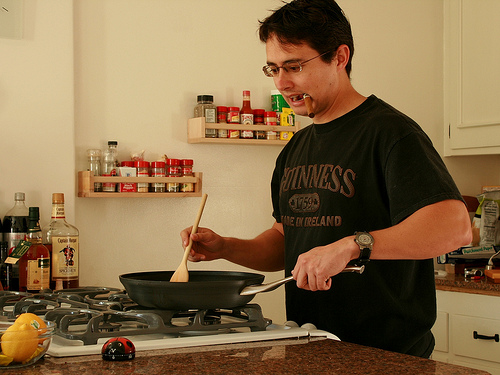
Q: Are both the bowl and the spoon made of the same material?
A: No, the bowl is made of glass and the spoon is made of wood.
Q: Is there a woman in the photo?
A: No, there are no women.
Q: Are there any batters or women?
A: No, there are no women or batters.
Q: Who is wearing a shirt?
A: The man is wearing a shirt.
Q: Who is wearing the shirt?
A: The man is wearing a shirt.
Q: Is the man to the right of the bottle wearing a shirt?
A: Yes, the man is wearing a shirt.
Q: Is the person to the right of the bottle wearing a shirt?
A: Yes, the man is wearing a shirt.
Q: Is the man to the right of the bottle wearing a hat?
A: No, the man is wearing a shirt.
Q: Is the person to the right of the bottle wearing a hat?
A: No, the man is wearing a shirt.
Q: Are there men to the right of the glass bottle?
A: Yes, there is a man to the right of the bottle.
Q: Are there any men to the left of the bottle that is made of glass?
A: No, the man is to the right of the bottle.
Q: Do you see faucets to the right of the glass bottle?
A: No, there is a man to the right of the bottle.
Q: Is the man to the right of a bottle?
A: Yes, the man is to the right of a bottle.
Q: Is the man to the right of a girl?
A: No, the man is to the right of a bottle.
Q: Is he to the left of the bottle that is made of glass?
A: No, the man is to the right of the bottle.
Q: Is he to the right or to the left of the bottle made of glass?
A: The man is to the right of the bottle.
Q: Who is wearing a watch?
A: The man is wearing a watch.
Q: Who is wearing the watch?
A: The man is wearing a watch.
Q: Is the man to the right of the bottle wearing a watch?
A: Yes, the man is wearing a watch.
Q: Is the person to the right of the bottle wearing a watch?
A: Yes, the man is wearing a watch.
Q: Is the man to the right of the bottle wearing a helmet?
A: No, the man is wearing a watch.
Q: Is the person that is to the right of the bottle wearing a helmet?
A: No, the man is wearing a watch.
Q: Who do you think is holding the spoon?
A: The man is holding the spoon.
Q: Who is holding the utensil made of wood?
A: The man is holding the spoon.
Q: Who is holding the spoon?
A: The man is holding the spoon.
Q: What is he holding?
A: The man is holding the spoon.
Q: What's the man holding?
A: The man is holding the spoon.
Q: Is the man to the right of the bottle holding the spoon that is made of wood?
A: Yes, the man is holding the spoon.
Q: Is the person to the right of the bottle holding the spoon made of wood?
A: Yes, the man is holding the spoon.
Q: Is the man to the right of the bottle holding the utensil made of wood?
A: Yes, the man is holding the spoon.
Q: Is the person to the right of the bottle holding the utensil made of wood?
A: Yes, the man is holding the spoon.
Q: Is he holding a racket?
A: No, the man is holding the spoon.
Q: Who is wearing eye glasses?
A: The man is wearing eye glasses.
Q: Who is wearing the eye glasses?
A: The man is wearing eye glasses.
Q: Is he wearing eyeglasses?
A: Yes, the man is wearing eyeglasses.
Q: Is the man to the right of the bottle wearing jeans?
A: No, the man is wearing eyeglasses.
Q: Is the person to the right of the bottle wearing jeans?
A: No, the man is wearing eyeglasses.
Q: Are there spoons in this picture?
A: Yes, there is a spoon.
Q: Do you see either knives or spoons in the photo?
A: Yes, there is a spoon.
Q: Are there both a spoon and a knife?
A: No, there is a spoon but no knives.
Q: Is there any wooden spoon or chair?
A: Yes, there is a wood spoon.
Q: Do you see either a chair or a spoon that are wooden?
A: Yes, the spoon is wooden.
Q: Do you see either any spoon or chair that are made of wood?
A: Yes, the spoon is made of wood.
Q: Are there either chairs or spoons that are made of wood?
A: Yes, the spoon is made of wood.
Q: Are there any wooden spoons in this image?
A: Yes, there is a wood spoon.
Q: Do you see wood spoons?
A: Yes, there is a wood spoon.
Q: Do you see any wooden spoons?
A: Yes, there is a wood spoon.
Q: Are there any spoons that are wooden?
A: Yes, there is a spoon that is wooden.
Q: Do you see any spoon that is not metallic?
A: Yes, there is a wooden spoon.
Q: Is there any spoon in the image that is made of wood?
A: Yes, there is a spoon that is made of wood.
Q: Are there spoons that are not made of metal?
A: Yes, there is a spoon that is made of wood.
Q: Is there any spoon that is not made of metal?
A: Yes, there is a spoon that is made of wood.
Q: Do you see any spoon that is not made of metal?
A: Yes, there is a spoon that is made of wood.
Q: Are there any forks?
A: No, there are no forks.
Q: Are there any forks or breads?
A: No, there are no forks or breads.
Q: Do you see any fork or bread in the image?
A: No, there are no forks or breads.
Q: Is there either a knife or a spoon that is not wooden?
A: No, there is a spoon but it is wooden.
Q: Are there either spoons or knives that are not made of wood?
A: No, there is a spoon but it is made of wood.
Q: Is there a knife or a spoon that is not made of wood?
A: No, there is a spoon but it is made of wood.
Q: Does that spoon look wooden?
A: Yes, the spoon is wooden.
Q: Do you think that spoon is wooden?
A: Yes, the spoon is wooden.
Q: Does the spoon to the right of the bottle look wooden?
A: Yes, the spoon is wooden.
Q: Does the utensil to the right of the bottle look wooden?
A: Yes, the spoon is wooden.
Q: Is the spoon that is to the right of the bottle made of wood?
A: Yes, the spoon is made of wood.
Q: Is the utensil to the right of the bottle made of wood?
A: Yes, the spoon is made of wood.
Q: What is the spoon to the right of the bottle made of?
A: The spoon is made of wood.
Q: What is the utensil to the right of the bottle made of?
A: The spoon is made of wood.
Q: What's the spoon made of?
A: The spoon is made of wood.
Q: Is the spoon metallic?
A: No, the spoon is wooden.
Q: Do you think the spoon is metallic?
A: No, the spoon is wooden.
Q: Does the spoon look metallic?
A: No, the spoon is wooden.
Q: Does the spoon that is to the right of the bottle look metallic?
A: No, the spoon is wooden.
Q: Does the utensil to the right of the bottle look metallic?
A: No, the spoon is wooden.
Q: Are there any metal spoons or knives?
A: No, there is a spoon but it is wooden.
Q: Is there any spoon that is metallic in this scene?
A: No, there is a spoon but it is wooden.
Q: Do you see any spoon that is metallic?
A: No, there is a spoon but it is wooden.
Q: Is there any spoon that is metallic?
A: No, there is a spoon but it is wooden.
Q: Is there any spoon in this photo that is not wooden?
A: No, there is a spoon but it is wooden.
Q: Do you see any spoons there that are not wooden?
A: No, there is a spoon but it is wooden.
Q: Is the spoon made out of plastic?
A: No, the spoon is made of wood.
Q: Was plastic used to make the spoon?
A: No, the spoon is made of wood.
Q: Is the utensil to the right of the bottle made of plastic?
A: No, the spoon is made of wood.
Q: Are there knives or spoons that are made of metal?
A: No, there is a spoon but it is made of wood.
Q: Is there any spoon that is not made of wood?
A: No, there is a spoon but it is made of wood.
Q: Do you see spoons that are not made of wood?
A: No, there is a spoon but it is made of wood.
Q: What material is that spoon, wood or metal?
A: The spoon is made of wood.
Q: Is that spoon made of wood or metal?
A: The spoon is made of wood.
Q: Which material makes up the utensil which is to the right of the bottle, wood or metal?
A: The spoon is made of wood.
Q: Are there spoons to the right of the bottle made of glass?
A: Yes, there is a spoon to the right of the bottle.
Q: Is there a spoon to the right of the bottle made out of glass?
A: Yes, there is a spoon to the right of the bottle.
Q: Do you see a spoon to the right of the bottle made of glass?
A: Yes, there is a spoon to the right of the bottle.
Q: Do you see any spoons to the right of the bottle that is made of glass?
A: Yes, there is a spoon to the right of the bottle.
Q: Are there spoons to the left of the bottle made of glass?
A: No, the spoon is to the right of the bottle.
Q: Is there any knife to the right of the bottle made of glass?
A: No, there is a spoon to the right of the bottle.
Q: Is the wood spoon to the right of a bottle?
A: Yes, the spoon is to the right of a bottle.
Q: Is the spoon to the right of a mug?
A: No, the spoon is to the right of a bottle.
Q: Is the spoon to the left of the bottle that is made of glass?
A: No, the spoon is to the right of the bottle.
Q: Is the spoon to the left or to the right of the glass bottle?
A: The spoon is to the right of the bottle.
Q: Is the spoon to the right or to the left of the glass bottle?
A: The spoon is to the right of the bottle.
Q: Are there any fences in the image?
A: No, there are no fences.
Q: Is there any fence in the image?
A: No, there are no fences.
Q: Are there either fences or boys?
A: No, there are no fences or boys.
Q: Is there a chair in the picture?
A: No, there are no chairs.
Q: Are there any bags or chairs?
A: No, there are no chairs or bags.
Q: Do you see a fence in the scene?
A: No, there are no fences.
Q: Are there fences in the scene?
A: No, there are no fences.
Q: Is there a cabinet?
A: Yes, there is a cabinet.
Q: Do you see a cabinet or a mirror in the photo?
A: Yes, there is a cabinet.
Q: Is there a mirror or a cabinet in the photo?
A: Yes, there is a cabinet.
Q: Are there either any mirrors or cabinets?
A: Yes, there is a cabinet.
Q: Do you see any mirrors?
A: No, there are no mirrors.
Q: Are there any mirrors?
A: No, there are no mirrors.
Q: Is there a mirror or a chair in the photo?
A: No, there are no mirrors or chairs.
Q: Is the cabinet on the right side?
A: Yes, the cabinet is on the right of the image.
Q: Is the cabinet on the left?
A: No, the cabinet is on the right of the image.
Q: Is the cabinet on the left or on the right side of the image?
A: The cabinet is on the right of the image.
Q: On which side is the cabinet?
A: The cabinet is on the right of the image.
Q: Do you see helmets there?
A: No, there are no helmets.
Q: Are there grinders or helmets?
A: No, there are no helmets or grinders.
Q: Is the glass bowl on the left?
A: Yes, the bowl is on the left of the image.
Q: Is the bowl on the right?
A: No, the bowl is on the left of the image.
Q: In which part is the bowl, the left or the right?
A: The bowl is on the left of the image.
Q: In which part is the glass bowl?
A: The bowl is on the left of the image.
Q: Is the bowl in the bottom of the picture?
A: Yes, the bowl is in the bottom of the image.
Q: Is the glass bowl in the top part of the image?
A: No, the bowl is in the bottom of the image.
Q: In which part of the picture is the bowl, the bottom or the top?
A: The bowl is in the bottom of the image.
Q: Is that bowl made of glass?
A: Yes, the bowl is made of glass.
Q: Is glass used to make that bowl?
A: Yes, the bowl is made of glass.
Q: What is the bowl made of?
A: The bowl is made of glass.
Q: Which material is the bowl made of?
A: The bowl is made of glass.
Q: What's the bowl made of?
A: The bowl is made of glass.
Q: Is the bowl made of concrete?
A: No, the bowl is made of glass.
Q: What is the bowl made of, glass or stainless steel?
A: The bowl is made of glass.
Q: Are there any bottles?
A: Yes, there is a bottle.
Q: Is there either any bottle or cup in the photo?
A: Yes, there is a bottle.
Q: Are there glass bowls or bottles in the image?
A: Yes, there is a glass bottle.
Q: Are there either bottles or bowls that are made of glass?
A: Yes, the bottle is made of glass.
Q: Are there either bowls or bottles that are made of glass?
A: Yes, the bottle is made of glass.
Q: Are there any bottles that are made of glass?
A: Yes, there is a bottle that is made of glass.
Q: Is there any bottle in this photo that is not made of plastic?
A: Yes, there is a bottle that is made of glass.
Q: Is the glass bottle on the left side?
A: Yes, the bottle is on the left of the image.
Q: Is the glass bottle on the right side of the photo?
A: No, the bottle is on the left of the image.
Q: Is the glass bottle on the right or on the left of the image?
A: The bottle is on the left of the image.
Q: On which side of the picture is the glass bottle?
A: The bottle is on the left of the image.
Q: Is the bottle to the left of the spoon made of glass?
A: Yes, the bottle is made of glass.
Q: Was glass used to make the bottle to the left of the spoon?
A: Yes, the bottle is made of glass.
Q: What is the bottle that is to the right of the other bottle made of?
A: The bottle is made of glass.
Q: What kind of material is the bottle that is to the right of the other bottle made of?
A: The bottle is made of glass.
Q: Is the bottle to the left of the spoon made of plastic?
A: No, the bottle is made of glass.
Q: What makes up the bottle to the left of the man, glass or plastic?
A: The bottle is made of glass.